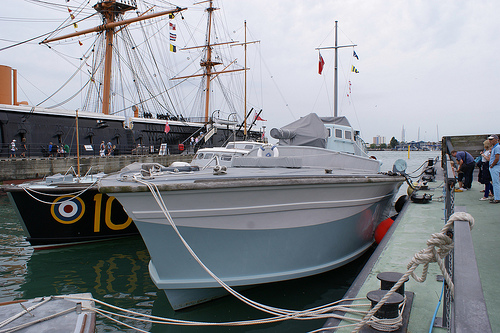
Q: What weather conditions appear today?
A: It is cloudy.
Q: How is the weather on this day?
A: It is cloudy.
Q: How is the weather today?
A: It is cloudy.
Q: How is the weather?
A: It is cloudy.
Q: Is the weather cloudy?
A: Yes, it is cloudy.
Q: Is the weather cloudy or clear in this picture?
A: It is cloudy.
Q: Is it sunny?
A: No, it is cloudy.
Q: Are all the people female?
A: No, they are both male and female.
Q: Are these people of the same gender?
A: No, they are both male and female.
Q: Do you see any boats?
A: Yes, there is a boat.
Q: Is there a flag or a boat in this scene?
A: Yes, there is a boat.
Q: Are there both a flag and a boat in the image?
A: Yes, there are both a boat and a flag.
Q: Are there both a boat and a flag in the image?
A: Yes, there are both a boat and a flag.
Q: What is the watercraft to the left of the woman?
A: The watercraft is a boat.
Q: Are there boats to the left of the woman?
A: Yes, there is a boat to the left of the woman.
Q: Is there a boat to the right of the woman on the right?
A: No, the boat is to the left of the woman.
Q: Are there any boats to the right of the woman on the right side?
A: No, the boat is to the left of the woman.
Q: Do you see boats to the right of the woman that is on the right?
A: No, the boat is to the left of the woman.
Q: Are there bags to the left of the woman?
A: No, there is a boat to the left of the woman.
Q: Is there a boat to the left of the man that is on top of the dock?
A: Yes, there is a boat to the left of the man.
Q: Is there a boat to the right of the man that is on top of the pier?
A: No, the boat is to the left of the man.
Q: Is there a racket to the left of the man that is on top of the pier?
A: No, there is a boat to the left of the man.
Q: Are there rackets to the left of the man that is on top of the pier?
A: No, there is a boat to the left of the man.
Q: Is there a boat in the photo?
A: Yes, there is a boat.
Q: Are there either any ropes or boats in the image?
A: Yes, there is a boat.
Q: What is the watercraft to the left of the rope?
A: The watercraft is a boat.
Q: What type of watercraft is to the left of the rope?
A: The watercraft is a boat.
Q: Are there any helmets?
A: No, there are no helmets.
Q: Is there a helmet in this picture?
A: No, there are no helmets.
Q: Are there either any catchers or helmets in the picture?
A: No, there are no helmets or catchers.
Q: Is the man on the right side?
A: Yes, the man is on the right of the image.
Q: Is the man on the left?
A: No, the man is on the right of the image.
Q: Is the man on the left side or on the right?
A: The man is on the right of the image.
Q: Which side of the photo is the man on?
A: The man is on the right of the image.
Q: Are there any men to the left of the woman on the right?
A: Yes, there is a man to the left of the woman.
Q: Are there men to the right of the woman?
A: No, the man is to the left of the woman.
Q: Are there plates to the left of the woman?
A: No, there is a man to the left of the woman.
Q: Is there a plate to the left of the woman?
A: No, there is a man to the left of the woman.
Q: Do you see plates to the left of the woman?
A: No, there is a man to the left of the woman.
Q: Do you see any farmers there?
A: No, there are no farmers.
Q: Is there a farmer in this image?
A: No, there are no farmers.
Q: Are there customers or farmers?
A: No, there are no farmers or customers.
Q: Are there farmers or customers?
A: No, there are no farmers or customers.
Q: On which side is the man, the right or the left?
A: The man is on the right of the image.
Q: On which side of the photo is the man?
A: The man is on the right of the image.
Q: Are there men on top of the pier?
A: Yes, there is a man on top of the pier.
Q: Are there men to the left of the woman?
A: Yes, there is a man to the left of the woman.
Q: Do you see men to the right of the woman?
A: No, the man is to the left of the woman.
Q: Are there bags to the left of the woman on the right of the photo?
A: No, there is a man to the left of the woman.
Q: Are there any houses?
A: No, there are no houses.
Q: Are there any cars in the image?
A: No, there are no cars.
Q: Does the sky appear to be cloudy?
A: Yes, the sky is cloudy.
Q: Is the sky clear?
A: No, the sky is cloudy.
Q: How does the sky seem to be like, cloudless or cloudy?
A: The sky is cloudy.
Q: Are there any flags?
A: Yes, there is a flag.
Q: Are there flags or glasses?
A: Yes, there is a flag.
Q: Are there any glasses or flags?
A: Yes, there is a flag.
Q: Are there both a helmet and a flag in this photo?
A: No, there is a flag but no helmets.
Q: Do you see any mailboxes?
A: No, there are no mailboxes.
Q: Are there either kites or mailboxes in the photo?
A: No, there are no mailboxes or kites.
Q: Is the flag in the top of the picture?
A: Yes, the flag is in the top of the image.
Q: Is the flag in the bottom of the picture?
A: No, the flag is in the top of the image.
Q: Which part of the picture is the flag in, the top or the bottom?
A: The flag is in the top of the image.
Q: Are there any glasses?
A: No, there are no glasses.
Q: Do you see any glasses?
A: No, there are no glasses.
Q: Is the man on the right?
A: Yes, the man is on the right of the image.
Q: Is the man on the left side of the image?
A: No, the man is on the right of the image.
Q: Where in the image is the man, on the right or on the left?
A: The man is on the right of the image.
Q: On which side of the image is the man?
A: The man is on the right of the image.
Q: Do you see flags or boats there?
A: Yes, there is a boat.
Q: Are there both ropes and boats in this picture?
A: Yes, there are both a boat and a rope.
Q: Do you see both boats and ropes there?
A: Yes, there are both a boat and a rope.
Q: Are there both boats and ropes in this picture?
A: Yes, there are both a boat and a rope.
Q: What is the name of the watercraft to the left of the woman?
A: The watercraft is a boat.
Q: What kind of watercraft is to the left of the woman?
A: The watercraft is a boat.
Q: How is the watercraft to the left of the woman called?
A: The watercraft is a boat.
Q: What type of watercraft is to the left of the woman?
A: The watercraft is a boat.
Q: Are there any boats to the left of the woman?
A: Yes, there is a boat to the left of the woman.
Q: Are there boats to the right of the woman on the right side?
A: No, the boat is to the left of the woman.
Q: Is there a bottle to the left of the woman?
A: No, there is a boat to the left of the woman.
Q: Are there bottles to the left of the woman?
A: No, there is a boat to the left of the woman.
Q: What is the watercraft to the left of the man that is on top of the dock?
A: The watercraft is a boat.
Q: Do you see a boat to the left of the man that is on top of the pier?
A: Yes, there is a boat to the left of the man.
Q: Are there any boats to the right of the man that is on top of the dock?
A: No, the boat is to the left of the man.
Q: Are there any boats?
A: Yes, there is a boat.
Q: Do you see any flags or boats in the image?
A: Yes, there is a boat.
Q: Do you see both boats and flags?
A: Yes, there are both a boat and a flag.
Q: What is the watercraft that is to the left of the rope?
A: The watercraft is a boat.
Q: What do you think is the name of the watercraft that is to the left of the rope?
A: The watercraft is a boat.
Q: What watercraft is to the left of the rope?
A: The watercraft is a boat.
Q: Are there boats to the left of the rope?
A: Yes, there is a boat to the left of the rope.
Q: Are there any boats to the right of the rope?
A: No, the boat is to the left of the rope.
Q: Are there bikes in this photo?
A: No, there are no bikes.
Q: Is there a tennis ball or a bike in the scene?
A: No, there are no bikes or tennis balls.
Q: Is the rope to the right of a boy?
A: No, the rope is to the right of the boat.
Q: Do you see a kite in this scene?
A: No, there are no kites.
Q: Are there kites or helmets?
A: No, there are no kites or helmets.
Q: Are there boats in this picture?
A: Yes, there is a boat.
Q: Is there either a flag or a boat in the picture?
A: Yes, there is a boat.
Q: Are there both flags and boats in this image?
A: Yes, there are both a boat and a flag.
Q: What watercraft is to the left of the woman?
A: The watercraft is a boat.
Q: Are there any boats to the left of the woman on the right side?
A: Yes, there is a boat to the left of the woman.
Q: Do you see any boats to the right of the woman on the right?
A: No, the boat is to the left of the woman.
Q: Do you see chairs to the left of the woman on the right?
A: No, there is a boat to the left of the woman.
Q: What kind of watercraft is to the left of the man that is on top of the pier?
A: The watercraft is a boat.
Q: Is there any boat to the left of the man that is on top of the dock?
A: Yes, there is a boat to the left of the man.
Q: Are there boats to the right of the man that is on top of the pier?
A: No, the boat is to the left of the man.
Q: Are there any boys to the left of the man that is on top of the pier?
A: No, there is a boat to the left of the man.